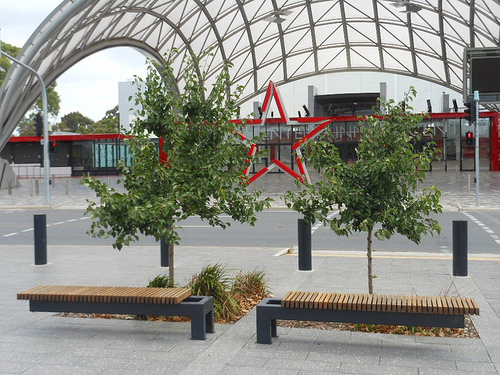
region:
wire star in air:
[199, 74, 339, 205]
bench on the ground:
[11, 282, 211, 327]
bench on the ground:
[242, 278, 484, 356]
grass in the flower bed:
[193, 266, 225, 315]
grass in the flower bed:
[234, 270, 261, 297]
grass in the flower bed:
[153, 275, 170, 287]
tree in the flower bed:
[106, 92, 222, 274]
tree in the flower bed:
[293, 95, 431, 290]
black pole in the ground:
[281, 216, 313, 275]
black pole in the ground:
[437, 214, 472, 291]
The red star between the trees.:
[214, 70, 334, 187]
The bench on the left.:
[17, 281, 217, 342]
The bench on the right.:
[248, 268, 479, 348]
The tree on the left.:
[85, 71, 257, 293]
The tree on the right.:
[288, 99, 454, 291]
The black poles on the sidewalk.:
[16, 197, 471, 292]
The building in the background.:
[3, 37, 491, 184]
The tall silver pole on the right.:
[473, 85, 483, 201]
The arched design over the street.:
[5, 1, 499, 118]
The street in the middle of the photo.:
[9, 193, 499, 250]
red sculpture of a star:
[230, 81, 320, 193]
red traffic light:
[464, 130, 474, 149]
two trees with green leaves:
[100, 40, 421, 303]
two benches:
[13, 281, 480, 344]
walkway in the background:
[64, 133, 118, 168]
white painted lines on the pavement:
[467, 208, 497, 248]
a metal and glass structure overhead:
[196, 2, 405, 72]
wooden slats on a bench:
[284, 289, 481, 316]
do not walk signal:
[465, 128, 477, 150]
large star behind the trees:
[223, 81, 339, 192]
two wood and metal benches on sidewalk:
[11, 277, 486, 351]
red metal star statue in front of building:
[211, 68, 337, 198]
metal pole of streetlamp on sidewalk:
[0, 43, 61, 207]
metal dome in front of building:
[2, 3, 495, 202]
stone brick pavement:
[1, 241, 496, 367]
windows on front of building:
[78, 141, 143, 170]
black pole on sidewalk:
[20, 211, 55, 269]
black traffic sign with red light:
[462, 126, 475, 149]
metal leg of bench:
[185, 311, 210, 345]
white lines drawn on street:
[2, 206, 114, 240]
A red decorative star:
[216, 81, 335, 191]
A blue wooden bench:
[255, 291, 480, 342]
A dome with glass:
[0, 0, 499, 185]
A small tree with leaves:
[277, 84, 443, 296]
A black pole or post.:
[34, 214, 46, 263]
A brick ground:
[0, 246, 499, 374]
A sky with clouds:
[0, 0, 175, 137]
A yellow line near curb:
[285, 251, 499, 265]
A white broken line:
[460, 209, 499, 252]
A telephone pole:
[0, 50, 51, 204]